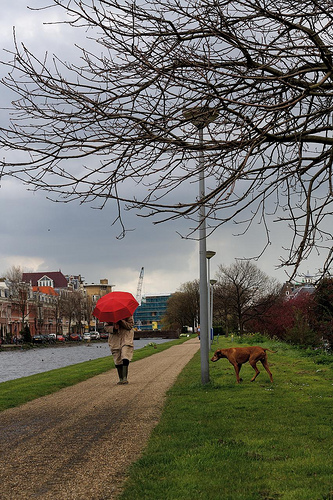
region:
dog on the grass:
[214, 345, 283, 387]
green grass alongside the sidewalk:
[188, 384, 309, 481]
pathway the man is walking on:
[33, 398, 114, 499]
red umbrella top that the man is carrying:
[95, 288, 145, 322]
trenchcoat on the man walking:
[103, 321, 146, 360]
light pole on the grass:
[192, 226, 219, 383]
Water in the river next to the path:
[10, 343, 80, 367]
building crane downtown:
[129, 271, 152, 294]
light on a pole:
[175, 94, 234, 130]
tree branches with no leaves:
[37, 94, 144, 199]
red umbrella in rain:
[89, 287, 141, 325]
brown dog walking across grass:
[211, 343, 281, 388]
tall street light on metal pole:
[175, 102, 221, 392]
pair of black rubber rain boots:
[110, 363, 132, 386]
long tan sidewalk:
[6, 351, 164, 494]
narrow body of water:
[2, 336, 109, 375]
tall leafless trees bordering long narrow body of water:
[6, 261, 39, 345]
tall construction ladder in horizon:
[133, 263, 147, 305]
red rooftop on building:
[21, 270, 70, 290]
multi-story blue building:
[131, 293, 171, 331]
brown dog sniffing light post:
[195, 329, 276, 389]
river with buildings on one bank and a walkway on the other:
[3, 323, 179, 382]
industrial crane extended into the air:
[125, 258, 149, 318]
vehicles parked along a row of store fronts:
[24, 332, 105, 342]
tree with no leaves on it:
[207, 252, 275, 340]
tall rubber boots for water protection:
[105, 357, 137, 388]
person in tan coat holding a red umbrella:
[93, 282, 139, 392]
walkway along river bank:
[11, 332, 205, 498]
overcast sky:
[9, 6, 328, 271]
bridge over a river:
[122, 324, 191, 339]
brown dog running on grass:
[197, 345, 294, 386]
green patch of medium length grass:
[193, 326, 326, 480]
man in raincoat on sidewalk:
[96, 279, 155, 400]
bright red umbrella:
[92, 285, 143, 331]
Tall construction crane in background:
[130, 263, 156, 299]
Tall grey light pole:
[171, 102, 219, 385]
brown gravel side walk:
[31, 370, 119, 488]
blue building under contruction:
[130, 296, 188, 332]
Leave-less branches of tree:
[92, 44, 331, 232]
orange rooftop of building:
[27, 281, 61, 294]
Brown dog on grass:
[210, 343, 282, 385]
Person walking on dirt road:
[87, 284, 148, 390]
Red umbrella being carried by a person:
[82, 282, 141, 326]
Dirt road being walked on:
[6, 331, 199, 497]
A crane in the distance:
[132, 264, 147, 302]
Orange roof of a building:
[29, 284, 60, 296]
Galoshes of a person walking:
[108, 363, 137, 386]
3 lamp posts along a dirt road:
[173, 93, 228, 389]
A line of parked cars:
[25, 329, 109, 344]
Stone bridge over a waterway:
[132, 326, 182, 342]